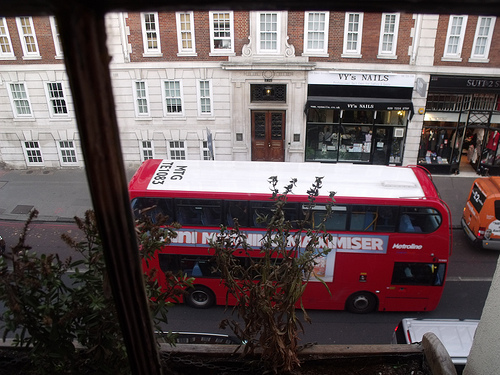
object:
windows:
[345, 203, 403, 235]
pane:
[220, 23, 224, 29]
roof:
[307, 68, 414, 89]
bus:
[122, 152, 457, 316]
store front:
[303, 82, 414, 165]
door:
[250, 107, 285, 161]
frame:
[251, 110, 286, 162]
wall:
[0, 9, 500, 169]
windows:
[254, 112, 266, 140]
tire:
[182, 282, 216, 310]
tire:
[343, 289, 380, 315]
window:
[207, 10, 237, 57]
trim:
[228, 10, 236, 52]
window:
[253, 11, 285, 58]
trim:
[255, 12, 261, 53]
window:
[300, 10, 332, 59]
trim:
[302, 10, 308, 57]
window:
[340, 11, 365, 60]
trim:
[342, 10, 349, 55]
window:
[375, 12, 402, 60]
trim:
[377, 13, 387, 57]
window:
[439, 13, 469, 62]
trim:
[456, 14, 469, 54]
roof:
[128, 158, 444, 208]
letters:
[170, 174, 182, 180]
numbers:
[152, 180, 165, 185]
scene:
[0, 9, 500, 315]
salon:
[303, 67, 431, 169]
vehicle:
[460, 175, 500, 252]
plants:
[0, 207, 89, 372]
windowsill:
[1, 331, 459, 375]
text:
[152, 161, 187, 184]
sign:
[148, 228, 389, 255]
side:
[126, 191, 453, 315]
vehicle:
[392, 313, 499, 375]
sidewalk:
[0, 166, 492, 230]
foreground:
[0, 219, 500, 375]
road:
[0, 169, 500, 372]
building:
[0, 7, 500, 169]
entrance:
[455, 126, 488, 174]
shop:
[415, 71, 500, 176]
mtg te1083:
[151, 161, 187, 185]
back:
[460, 178, 492, 242]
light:
[476, 227, 485, 240]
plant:
[203, 173, 337, 375]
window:
[1, 0, 500, 375]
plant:
[60, 205, 186, 375]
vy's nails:
[338, 73, 389, 82]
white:
[307, 69, 417, 88]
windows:
[14, 15, 43, 60]